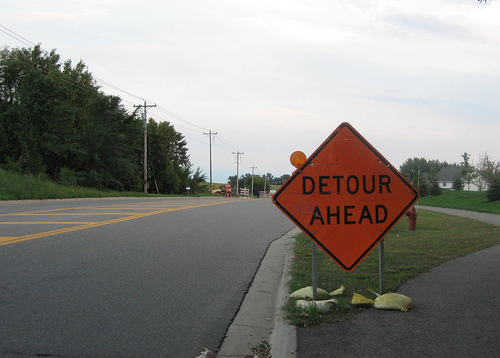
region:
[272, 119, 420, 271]
An orange Detour sign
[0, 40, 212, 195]
Green leaves on many trees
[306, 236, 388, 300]
Two gray posts holding up a sign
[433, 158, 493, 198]
A house is white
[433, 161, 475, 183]
Gray roof of a house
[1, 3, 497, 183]
The sky appears overcast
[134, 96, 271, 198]
Five telephone poles in a row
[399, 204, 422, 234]
A red fire hydrant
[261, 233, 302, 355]
The curb of a sidewalk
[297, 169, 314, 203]
Black lettering on an orange sign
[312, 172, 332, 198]
Black lettering on an orange sign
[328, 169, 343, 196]
Black lettering on an orange sign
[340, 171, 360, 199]
Black lettering on an orange sign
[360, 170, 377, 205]
Black lettering on an orange sign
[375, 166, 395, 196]
Black lettering on an orange sign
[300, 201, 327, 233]
Black lettering on an orange sign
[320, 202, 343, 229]
Black lettering on an orange sign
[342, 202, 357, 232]
Black lettering on an orange sign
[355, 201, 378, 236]
Black lettering on an orange sign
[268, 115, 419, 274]
sign is orange and black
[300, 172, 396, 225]
black letters on sign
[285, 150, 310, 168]
orange light on sign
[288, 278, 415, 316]
bags underneath the sign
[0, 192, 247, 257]
yellow lines in road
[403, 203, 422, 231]
fire hydrant in grass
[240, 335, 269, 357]
grass on the side pavement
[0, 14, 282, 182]
electrical wires attached to poles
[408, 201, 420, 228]
fire hydrant is red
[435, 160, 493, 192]
white house in distance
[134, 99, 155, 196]
brown wood electrical pole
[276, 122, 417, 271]
orange and black sign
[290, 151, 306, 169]
orange reflector on sign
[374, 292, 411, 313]
sand bag on ground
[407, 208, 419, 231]
red fire hydrant in grass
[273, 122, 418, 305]
detour sign on ground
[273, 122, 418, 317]
construction sign on ground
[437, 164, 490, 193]
white and grey house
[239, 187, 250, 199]
barrier construction sign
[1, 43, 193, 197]
trees with green leaves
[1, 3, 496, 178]
light blue sky covered with streaky white clouds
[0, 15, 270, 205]
trees behind poles with electrical wires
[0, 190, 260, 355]
dark paved street with lines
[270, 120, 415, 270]
orange traffic sign with orange light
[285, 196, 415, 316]
weighted bags around poles supporting sign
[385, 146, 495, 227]
trees surrounding white house behind sidewalk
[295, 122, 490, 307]
red fire hydrant on triangle of grass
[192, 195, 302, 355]
gray border between street and grassy curb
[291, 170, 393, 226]
one word on top of another word